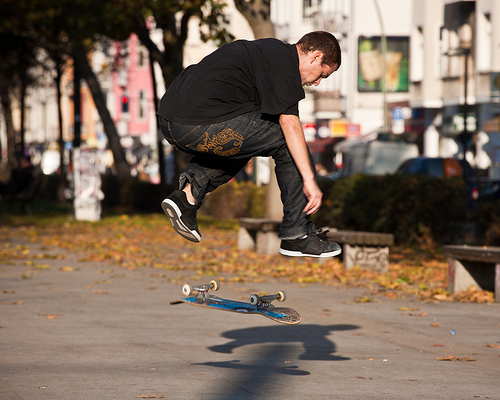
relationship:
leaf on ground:
[57, 263, 83, 276] [1, 203, 498, 399]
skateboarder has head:
[143, 24, 365, 261] [296, 29, 347, 91]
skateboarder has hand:
[143, 24, 365, 261] [298, 173, 329, 221]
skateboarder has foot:
[143, 24, 365, 261] [157, 188, 206, 246]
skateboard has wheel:
[164, 273, 305, 327] [178, 279, 193, 299]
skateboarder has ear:
[143, 24, 365, 261] [308, 50, 326, 63]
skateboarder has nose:
[143, 24, 365, 261] [309, 77, 324, 88]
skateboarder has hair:
[143, 24, 365, 261] [298, 29, 345, 72]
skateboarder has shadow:
[143, 24, 365, 261] [184, 315, 361, 378]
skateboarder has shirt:
[143, 24, 365, 261] [149, 35, 306, 128]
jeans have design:
[155, 106, 322, 239] [192, 124, 248, 159]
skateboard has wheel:
[164, 273, 305, 327] [246, 290, 261, 305]